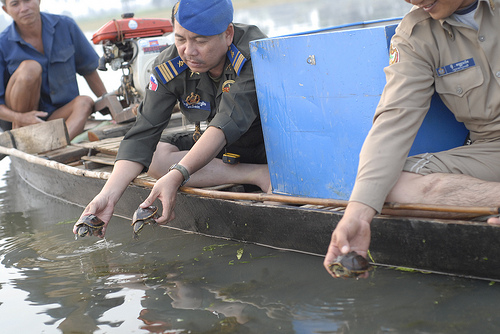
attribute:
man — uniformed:
[70, 0, 268, 237]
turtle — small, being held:
[76, 213, 107, 241]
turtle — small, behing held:
[130, 205, 160, 239]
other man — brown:
[321, 1, 499, 281]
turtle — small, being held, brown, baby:
[330, 251, 373, 282]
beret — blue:
[177, 1, 235, 36]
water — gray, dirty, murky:
[0, 154, 499, 332]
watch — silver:
[169, 161, 191, 184]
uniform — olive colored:
[113, 24, 274, 169]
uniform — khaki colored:
[348, 0, 500, 216]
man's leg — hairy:
[389, 170, 500, 212]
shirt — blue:
[0, 12, 103, 122]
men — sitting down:
[0, 1, 497, 280]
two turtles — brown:
[73, 206, 160, 240]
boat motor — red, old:
[92, 11, 175, 99]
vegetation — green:
[204, 237, 257, 266]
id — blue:
[435, 54, 478, 80]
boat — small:
[0, 11, 497, 283]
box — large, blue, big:
[248, 16, 469, 201]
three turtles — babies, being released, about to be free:
[75, 204, 373, 282]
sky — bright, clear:
[1, 2, 417, 121]